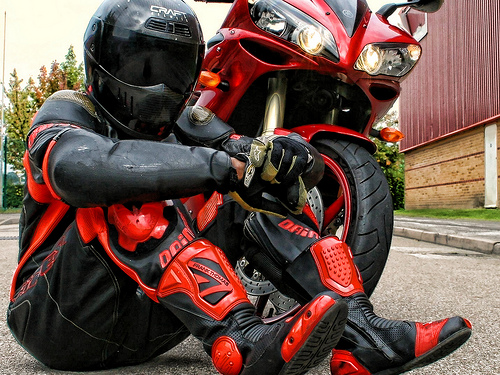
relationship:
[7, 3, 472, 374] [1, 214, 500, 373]
bike rider sits on pavement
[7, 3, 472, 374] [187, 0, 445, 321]
bike rider seated in front of motorcycle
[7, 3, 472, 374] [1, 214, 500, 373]
bike rider sitting on ground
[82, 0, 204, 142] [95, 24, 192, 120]
helmet covers face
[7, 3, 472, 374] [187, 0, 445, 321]
bike rider sitting next to motorcycle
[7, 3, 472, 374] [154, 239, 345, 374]
bike rider wearing boots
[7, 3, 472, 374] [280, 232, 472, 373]
bike rider wearing boots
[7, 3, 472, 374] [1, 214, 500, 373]
bike rider sitting on road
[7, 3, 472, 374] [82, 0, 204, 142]
bike rider wearing helmet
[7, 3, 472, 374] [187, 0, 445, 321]
bike rider next to motorcycle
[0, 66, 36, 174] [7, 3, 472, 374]
tree behind bike rider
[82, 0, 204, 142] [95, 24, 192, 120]
helmet covering face